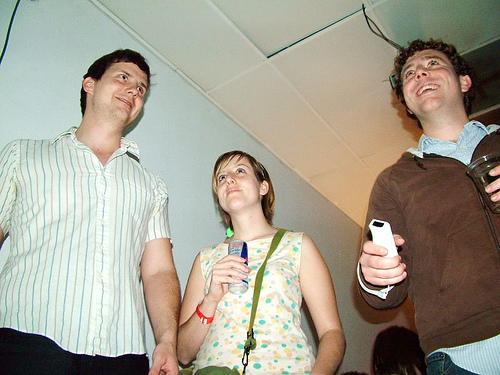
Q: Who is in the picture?
A: Two men and one woman.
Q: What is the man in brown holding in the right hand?
A: A wii.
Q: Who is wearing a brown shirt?
A: A man.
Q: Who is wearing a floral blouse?
A: A woman.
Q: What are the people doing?
A: Having fun.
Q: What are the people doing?
A: Smiling.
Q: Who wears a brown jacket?
A: A man.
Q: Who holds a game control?
A: A man.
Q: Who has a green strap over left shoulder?
A: A woman.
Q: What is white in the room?
A: Ceiling.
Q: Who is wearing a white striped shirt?
A: The man on the left.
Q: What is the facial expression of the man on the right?
A: He is smiling.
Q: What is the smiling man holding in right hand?
A: A wiimote.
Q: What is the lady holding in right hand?
A: A can of soda.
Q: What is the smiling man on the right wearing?
A: A brown jacket.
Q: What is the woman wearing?
A: A spotted shirt.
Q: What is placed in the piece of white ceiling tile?
A: A cord.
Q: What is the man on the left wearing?
A: A short sleeve shirt.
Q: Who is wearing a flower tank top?
A: A woman.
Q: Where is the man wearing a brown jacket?
A: On the right.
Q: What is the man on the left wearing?
A: Striped shirt.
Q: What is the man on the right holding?
A: A wii remote.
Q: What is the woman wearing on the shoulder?
A: Purse.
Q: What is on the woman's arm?
A: An orange bracelet.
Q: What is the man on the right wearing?
A: A brown jacket.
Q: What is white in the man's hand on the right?
A: The wii remote.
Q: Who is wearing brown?
A: A guy.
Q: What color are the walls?
A: White.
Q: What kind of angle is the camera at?
A: Low angle.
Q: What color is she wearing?
A: White.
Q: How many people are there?
A: Four.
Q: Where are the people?
A: At a party.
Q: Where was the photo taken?
A: At an office party.